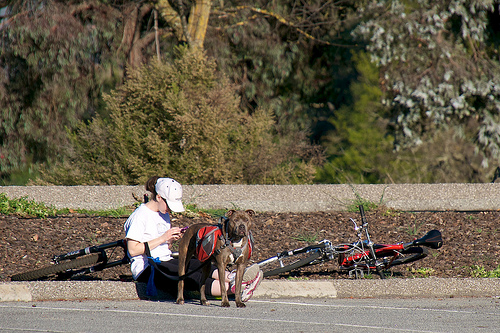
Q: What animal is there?
A: Dog.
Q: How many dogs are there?
A: One.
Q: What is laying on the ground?
A: Bikes.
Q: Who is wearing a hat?
A: THe woman.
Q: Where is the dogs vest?
A: On its body.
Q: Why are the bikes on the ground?
A: Not in use.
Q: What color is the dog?
A: Brown.